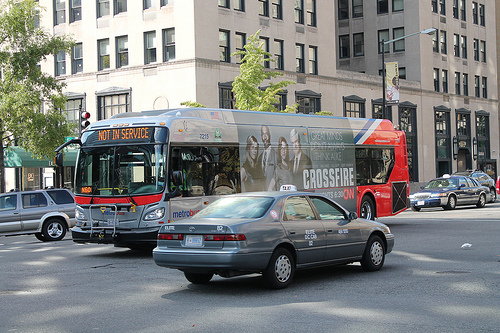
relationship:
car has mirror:
[148, 186, 399, 290] [345, 199, 360, 227]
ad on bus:
[232, 105, 363, 225] [68, 102, 411, 253]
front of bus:
[67, 104, 175, 257] [68, 102, 411, 253]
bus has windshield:
[68, 102, 411, 253] [69, 127, 173, 201]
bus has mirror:
[68, 102, 411, 253] [52, 132, 83, 174]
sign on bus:
[82, 121, 162, 150] [68, 102, 411, 253]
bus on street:
[68, 102, 411, 253] [0, 195, 499, 332]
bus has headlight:
[68, 102, 411, 253] [73, 205, 92, 224]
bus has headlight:
[68, 102, 411, 253] [133, 199, 178, 223]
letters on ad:
[295, 162, 356, 188] [232, 105, 363, 225]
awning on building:
[1, 130, 91, 178] [2, 0, 500, 221]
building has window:
[2, 0, 500, 221] [53, 2, 67, 30]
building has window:
[2, 0, 500, 221] [52, 40, 68, 80]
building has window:
[2, 0, 500, 221] [70, 37, 86, 79]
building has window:
[2, 0, 500, 221] [94, 33, 113, 77]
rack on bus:
[83, 197, 122, 245] [68, 102, 411, 253]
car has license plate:
[148, 186, 399, 290] [179, 231, 212, 249]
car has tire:
[148, 186, 399, 290] [358, 228, 392, 273]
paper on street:
[455, 235, 477, 254] [0, 195, 499, 332]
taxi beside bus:
[148, 186, 399, 290] [68, 102, 411, 253]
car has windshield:
[148, 186, 399, 290] [190, 191, 280, 226]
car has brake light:
[148, 186, 399, 290] [156, 228, 185, 243]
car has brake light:
[148, 186, 399, 290] [203, 228, 249, 247]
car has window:
[148, 186, 399, 290] [300, 191, 353, 223]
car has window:
[148, 186, 399, 290] [273, 192, 319, 223]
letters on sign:
[97, 127, 150, 140] [82, 121, 162, 150]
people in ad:
[244, 124, 305, 168] [232, 105, 363, 225]